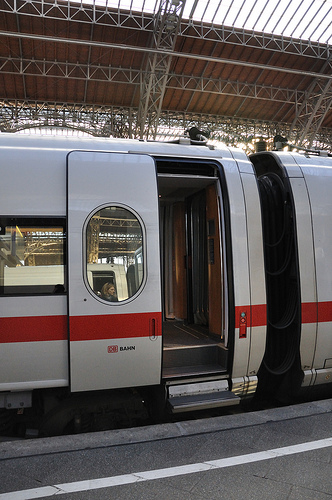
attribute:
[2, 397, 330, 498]
sidewalk — paved, platform, straight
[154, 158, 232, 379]
door — open, sliding, red, metal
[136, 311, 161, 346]
handle — red, silver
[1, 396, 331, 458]
curb — gray, straight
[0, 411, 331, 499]
sidewalk — gray, straight, paved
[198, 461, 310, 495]
cracks — small, straight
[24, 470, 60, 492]
cracks — straight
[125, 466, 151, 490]
cracks — straight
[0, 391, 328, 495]
pavement — gray, concrete, platform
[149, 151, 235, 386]
doorway — open, narrow, dark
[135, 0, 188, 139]
cables — silver 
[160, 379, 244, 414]
steps — silver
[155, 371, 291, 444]
step — silver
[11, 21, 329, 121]
ceiling — red 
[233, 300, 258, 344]
buttons — red, green, round, silver, stopped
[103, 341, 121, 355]
symbol — small, red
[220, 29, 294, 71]
bridge —  for suspension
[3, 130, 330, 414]
cars — silver, red, connected, buffered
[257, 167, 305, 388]
hose — black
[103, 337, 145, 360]
logo — red, black, design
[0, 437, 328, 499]
line — white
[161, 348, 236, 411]
steps — silver, up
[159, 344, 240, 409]
stairs — silver, up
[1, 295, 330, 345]
stripe — red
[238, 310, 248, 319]
green light — small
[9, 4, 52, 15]
truss — bridge's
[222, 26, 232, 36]
truss — bridge's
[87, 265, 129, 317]
woman — standing, waiting, looking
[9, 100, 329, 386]
train — stopped, silver, red, long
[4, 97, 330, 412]
train — long, stopped,  subway's, red, silver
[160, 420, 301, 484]
paint — white, straight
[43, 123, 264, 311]
train — stopped, silver, red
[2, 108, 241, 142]
metal rafters — high, long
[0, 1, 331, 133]
roof — rusty, metal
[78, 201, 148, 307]
window — closed, glass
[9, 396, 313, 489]
ground — paved, concrete, platform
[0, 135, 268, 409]
train — red, stopped, empty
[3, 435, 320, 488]
line — white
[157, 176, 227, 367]
hallway — narrow, dark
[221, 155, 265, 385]
train — red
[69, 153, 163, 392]
door — red, silver, open, rectangular, slid